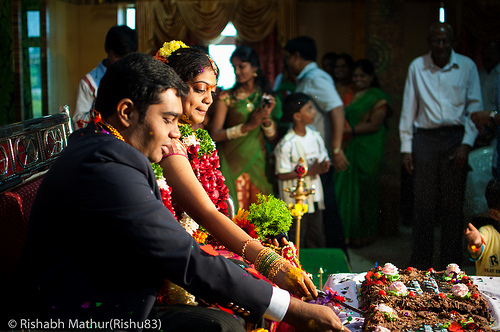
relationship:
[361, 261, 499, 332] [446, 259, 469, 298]
cake has flowers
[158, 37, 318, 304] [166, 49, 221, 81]
lady has hair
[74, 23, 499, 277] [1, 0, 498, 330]
guests are at reception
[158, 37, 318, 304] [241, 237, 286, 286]
woman has bracelets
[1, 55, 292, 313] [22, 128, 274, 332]
man wears suit